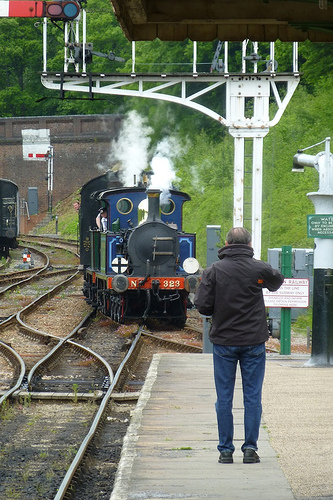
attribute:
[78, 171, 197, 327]
train — approaching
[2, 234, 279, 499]
ground — crisscrossing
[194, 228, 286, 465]
man — standing, waiting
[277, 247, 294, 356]
pole — green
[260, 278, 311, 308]
sign — red, white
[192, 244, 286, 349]
jacket — black, worn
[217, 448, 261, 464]
shoes — black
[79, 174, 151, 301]
caboose — blue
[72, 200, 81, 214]
man — looking